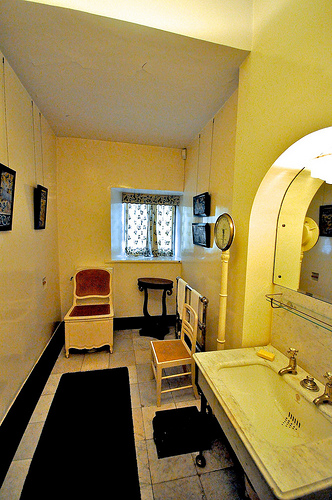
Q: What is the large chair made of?
A: Wood.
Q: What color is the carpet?
A: Black.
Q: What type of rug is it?
A: A shag black runner rug.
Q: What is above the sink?
A: A lighted mirror.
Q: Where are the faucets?
A: On the bathroom sink.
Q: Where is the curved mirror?
A: Over a sink.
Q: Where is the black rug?
A: On a tile floor.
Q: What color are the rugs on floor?
A: Black.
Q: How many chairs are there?
A: Two.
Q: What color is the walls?
A: Yellow.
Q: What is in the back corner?
A: A table.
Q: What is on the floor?
A: A rug.